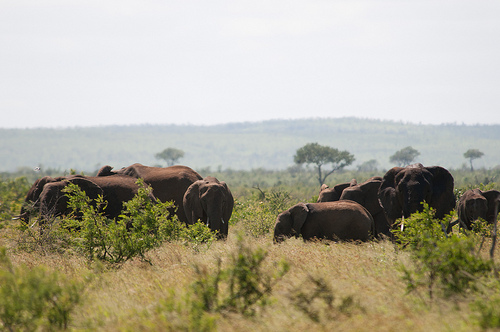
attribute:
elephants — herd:
[21, 140, 499, 242]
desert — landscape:
[0, 165, 499, 331]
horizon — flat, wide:
[0, 114, 497, 165]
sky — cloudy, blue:
[2, 4, 499, 120]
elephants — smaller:
[13, 156, 237, 250]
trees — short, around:
[288, 137, 422, 173]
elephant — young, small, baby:
[268, 194, 378, 248]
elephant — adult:
[30, 172, 149, 222]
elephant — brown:
[95, 160, 206, 223]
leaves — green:
[430, 240, 459, 268]